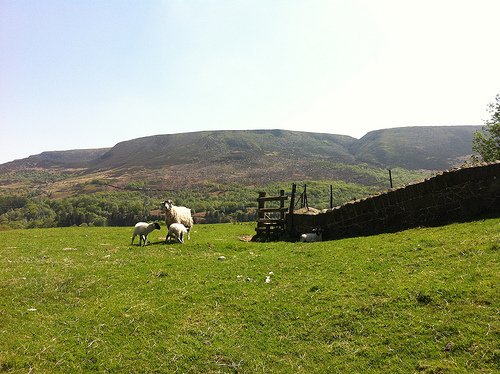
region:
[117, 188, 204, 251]
Sheeps on the prairie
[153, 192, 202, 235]
Big sheep near lambs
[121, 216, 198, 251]
Two lambs near an adult sheep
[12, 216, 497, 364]
Field is cover with green grass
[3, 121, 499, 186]
Hills on the background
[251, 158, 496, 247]
Fence on side of field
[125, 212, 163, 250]
Lamb face right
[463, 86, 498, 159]
Tree inside a fence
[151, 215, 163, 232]
Black head of lamb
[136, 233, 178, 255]
Shadow of sheeps cast on green grass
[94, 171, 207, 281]
Sheeps are on the field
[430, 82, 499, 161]
Trees on the gate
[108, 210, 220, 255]
Baby on the fields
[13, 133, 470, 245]
The hills in the background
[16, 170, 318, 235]
Grass bushes by the hills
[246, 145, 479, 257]
A fence on the side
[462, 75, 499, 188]
Trees on the side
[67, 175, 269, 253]
The only animals here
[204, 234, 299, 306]
white plants on the ground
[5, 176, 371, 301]
Bushes on the ground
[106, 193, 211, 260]
three sheep standing in a field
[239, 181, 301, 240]
a wooden fence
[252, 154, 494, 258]
a wall made of rocks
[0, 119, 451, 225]
several moutains covered in trees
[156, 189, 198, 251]
a baby sheep nursing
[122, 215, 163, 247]
a sheep with a black face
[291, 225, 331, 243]
a sheep sitting down on the ground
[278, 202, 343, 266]
a sheep next to a rock wall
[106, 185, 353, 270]
four sheep in a field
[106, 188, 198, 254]
a sheep with two baby shee[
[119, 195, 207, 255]
Three white sheep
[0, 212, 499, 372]
Large green pasture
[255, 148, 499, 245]
Brown stone wall bordering grass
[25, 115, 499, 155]
Green hills on the horizon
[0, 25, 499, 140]
Sky goes from blue to white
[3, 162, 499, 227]
Trees in the valley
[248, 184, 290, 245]
Log gate on wall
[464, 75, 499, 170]
Green tree behind stone wall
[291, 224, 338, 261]
One sheep laying in shadow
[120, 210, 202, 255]
Two sheep are babies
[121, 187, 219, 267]
the sheep are in the pasture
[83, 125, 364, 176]
the mountain is in the background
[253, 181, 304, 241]
the fence has cross bars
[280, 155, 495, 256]
the wall appears to be made of stone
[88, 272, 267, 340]
the grass is very green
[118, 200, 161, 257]
the lamb has a black face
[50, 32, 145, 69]
the sky is blue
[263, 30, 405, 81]
this part of the sky is more cloudy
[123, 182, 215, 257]
three sheep are in the photo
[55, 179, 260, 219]
trees are in the background